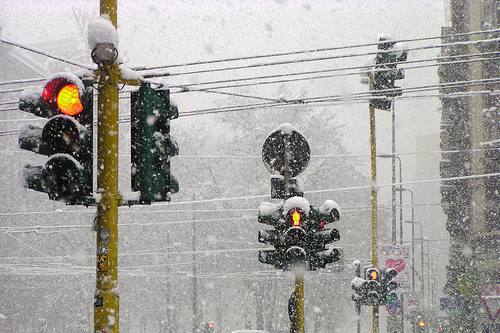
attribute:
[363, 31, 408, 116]
traffic signal — electric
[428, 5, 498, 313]
building — tall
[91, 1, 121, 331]
pole — yellow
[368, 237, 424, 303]
sign — red, white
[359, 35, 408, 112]
street light — snow covered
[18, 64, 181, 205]
traffic light — street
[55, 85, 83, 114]
light — yellow, traffic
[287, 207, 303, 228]
light — yellow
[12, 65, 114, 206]
light — traffic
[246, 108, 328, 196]
sign — round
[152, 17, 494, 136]
wire — telephone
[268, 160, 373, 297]
traffic signal — electric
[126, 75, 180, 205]
traffic signal — electric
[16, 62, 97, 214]
traffic signal — electric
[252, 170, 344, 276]
traffic signal — electric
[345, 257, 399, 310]
traffic signal — electric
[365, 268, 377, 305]
traffic signal — electric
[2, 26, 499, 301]
power line — snow covered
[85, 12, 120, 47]
snow — yellow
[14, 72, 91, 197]
signal — electric, traffic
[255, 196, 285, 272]
traffic signal — electric